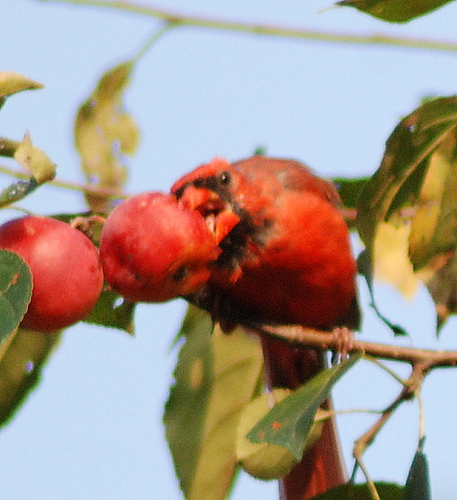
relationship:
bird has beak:
[170, 158, 360, 500] [181, 189, 240, 245]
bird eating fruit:
[170, 158, 360, 500] [101, 193, 218, 304]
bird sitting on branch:
[170, 158, 360, 500] [185, 294, 456, 366]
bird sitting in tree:
[170, 158, 360, 500] [0, 0, 455, 499]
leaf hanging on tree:
[0, 250, 33, 360] [0, 0, 455, 499]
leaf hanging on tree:
[50, 215, 137, 338] [0, 0, 455, 499]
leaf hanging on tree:
[246, 351, 364, 463] [0, 0, 455, 499]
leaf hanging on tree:
[338, 1, 451, 24] [0, 0, 455, 499]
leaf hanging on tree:
[356, 95, 456, 340] [0, 0, 455, 499]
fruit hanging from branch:
[101, 193, 218, 304] [185, 294, 456, 366]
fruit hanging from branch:
[0, 214, 103, 332] [185, 294, 456, 366]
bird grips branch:
[170, 158, 360, 500] [185, 294, 456, 366]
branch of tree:
[185, 294, 456, 366] [0, 0, 455, 499]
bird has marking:
[170, 158, 360, 500] [174, 176, 253, 261]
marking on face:
[174, 176, 253, 261] [170, 157, 271, 262]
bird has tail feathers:
[170, 158, 360, 500] [263, 333, 347, 499]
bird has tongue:
[170, 158, 360, 500] [205, 213, 217, 231]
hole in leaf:
[113, 296, 125, 309] [50, 215, 137, 338]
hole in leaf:
[410, 123, 418, 132] [356, 95, 456, 340]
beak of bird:
[181, 189, 240, 245] [170, 158, 360, 500]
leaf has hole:
[50, 215, 137, 338] [113, 296, 125, 309]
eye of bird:
[220, 172, 229, 185] [170, 158, 360, 500]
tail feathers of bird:
[263, 333, 347, 499] [170, 158, 360, 500]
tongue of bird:
[205, 213, 217, 231] [170, 158, 360, 500]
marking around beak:
[174, 176, 253, 261] [181, 189, 240, 245]